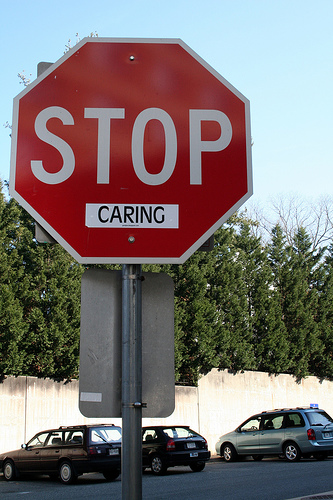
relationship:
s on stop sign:
[33, 112, 74, 184] [7, 29, 256, 266]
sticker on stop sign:
[89, 203, 174, 227] [17, 41, 240, 258]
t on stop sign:
[81, 105, 117, 186] [17, 41, 240, 258]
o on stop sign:
[128, 101, 178, 187] [17, 41, 240, 258]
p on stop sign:
[185, 103, 232, 197] [17, 41, 240, 258]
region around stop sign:
[2, 9, 314, 389] [17, 41, 240, 258]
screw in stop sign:
[126, 237, 134, 246] [17, 41, 240, 258]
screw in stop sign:
[125, 51, 137, 67] [17, 41, 240, 258]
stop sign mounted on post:
[17, 41, 240, 258] [121, 262, 144, 498]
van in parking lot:
[207, 416, 329, 453] [10, 396, 306, 498]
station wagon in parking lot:
[0, 421, 125, 494] [10, 396, 306, 498]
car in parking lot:
[141, 410, 223, 477] [10, 396, 306, 498]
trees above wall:
[3, 192, 319, 367] [7, 358, 331, 452]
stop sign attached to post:
[7, 29, 256, 266] [121, 262, 144, 498]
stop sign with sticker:
[17, 41, 240, 258] [89, 203, 174, 227]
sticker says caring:
[89, 203, 174, 227] [97, 207, 172, 221]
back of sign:
[84, 274, 173, 371] [91, 266, 160, 368]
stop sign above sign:
[17, 41, 240, 258] [91, 266, 160, 368]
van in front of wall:
[215, 401, 333, 462] [7, 358, 331, 452]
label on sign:
[75, 393, 110, 410] [91, 266, 160, 368]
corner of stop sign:
[28, 225, 51, 250] [7, 29, 256, 266]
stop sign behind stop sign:
[7, 29, 256, 266] [17, 41, 240, 258]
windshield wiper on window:
[97, 426, 113, 445] [87, 430, 126, 444]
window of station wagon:
[87, 430, 126, 444] [0, 421, 125, 494]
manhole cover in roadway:
[301, 489, 333, 497] [249, 452, 327, 496]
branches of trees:
[315, 212, 333, 242] [3, 192, 319, 367]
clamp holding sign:
[114, 271, 153, 283] [91, 266, 160, 368]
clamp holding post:
[114, 271, 153, 283] [121, 262, 144, 371]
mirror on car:
[162, 432, 174, 437] [141, 410, 223, 477]